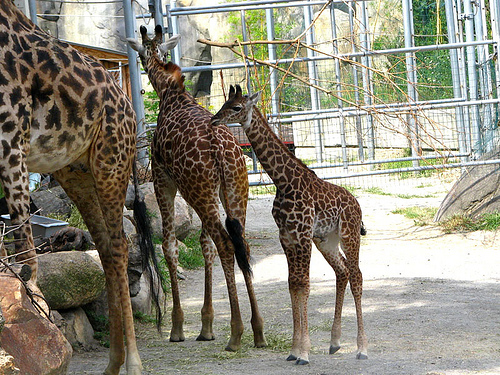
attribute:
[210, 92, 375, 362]
giraffe — standing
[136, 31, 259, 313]
giraffe — older, looking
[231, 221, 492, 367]
ground — sandy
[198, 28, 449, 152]
branch — large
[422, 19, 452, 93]
vegetation — green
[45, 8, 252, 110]
wall — rock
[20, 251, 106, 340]
stone — large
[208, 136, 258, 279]
tail — black, long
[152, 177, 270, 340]
legs — long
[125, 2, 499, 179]
gate — metal, tall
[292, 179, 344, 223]
spots — brown